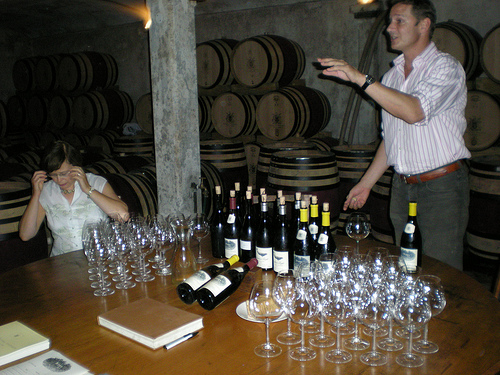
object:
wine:
[175, 180, 424, 311]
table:
[0, 198, 500, 375]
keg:
[190, 36, 330, 147]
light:
[122, 1, 150, 31]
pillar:
[144, 0, 203, 222]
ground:
[372, 117, 480, 194]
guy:
[311, 0, 475, 272]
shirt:
[378, 41, 472, 178]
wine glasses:
[246, 245, 446, 367]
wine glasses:
[81, 210, 211, 298]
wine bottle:
[207, 182, 336, 279]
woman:
[17, 139, 128, 256]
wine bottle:
[396, 199, 422, 273]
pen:
[163, 330, 200, 350]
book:
[98, 296, 204, 352]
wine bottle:
[177, 255, 260, 310]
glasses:
[45, 167, 72, 177]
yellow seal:
[407, 203, 418, 217]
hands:
[30, 166, 90, 190]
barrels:
[0, 0, 500, 286]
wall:
[0, 0, 500, 156]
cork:
[215, 182, 335, 212]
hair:
[39, 139, 86, 174]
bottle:
[175, 183, 423, 309]